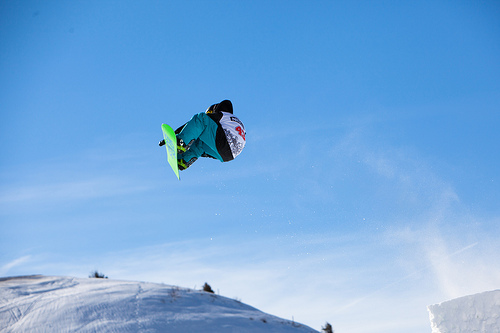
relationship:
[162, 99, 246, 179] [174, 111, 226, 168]
snowboarder wearing pants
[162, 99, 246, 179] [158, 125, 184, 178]
snowboarder riding snowboard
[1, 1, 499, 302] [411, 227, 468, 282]
sky has clouds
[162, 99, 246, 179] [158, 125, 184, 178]
snowboarder on snowboard